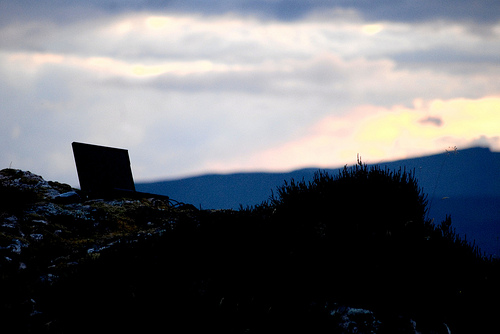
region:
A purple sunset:
[320, 86, 499, 163]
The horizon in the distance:
[135, 130, 497, 198]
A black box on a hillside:
[69, 137, 172, 221]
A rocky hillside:
[3, 162, 204, 329]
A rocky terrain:
[5, 168, 200, 332]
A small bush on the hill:
[255, 157, 450, 262]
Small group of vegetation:
[253, 164, 440, 259]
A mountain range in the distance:
[167, 144, 498, 182]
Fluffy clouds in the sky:
[17, 9, 392, 109]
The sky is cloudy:
[22, 12, 470, 124]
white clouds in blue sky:
[6, 15, 98, 65]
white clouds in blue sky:
[28, 58, 92, 109]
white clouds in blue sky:
[18, 101, 50, 166]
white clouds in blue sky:
[49, 5, 129, 62]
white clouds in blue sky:
[76, 78, 134, 113]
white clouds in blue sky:
[126, 62, 198, 150]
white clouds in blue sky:
[188, 25, 275, 105]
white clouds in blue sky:
[315, 35, 372, 93]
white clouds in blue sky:
[268, 48, 373, 145]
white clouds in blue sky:
[393, 11, 473, 111]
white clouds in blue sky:
[11, 42, 98, 90]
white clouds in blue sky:
[74, 76, 116, 98]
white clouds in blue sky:
[105, 26, 173, 75]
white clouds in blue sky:
[122, 74, 210, 116]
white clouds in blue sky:
[213, 78, 272, 141]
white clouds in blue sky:
[301, 31, 350, 86]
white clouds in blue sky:
[291, 87, 340, 137]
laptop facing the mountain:
[57, 132, 174, 219]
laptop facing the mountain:
[37, 61, 499, 248]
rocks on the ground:
[47, 189, 89, 219]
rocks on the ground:
[32, 181, 101, 230]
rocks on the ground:
[63, 186, 145, 262]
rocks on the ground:
[4, 207, 36, 254]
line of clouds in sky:
[16, 10, 492, 112]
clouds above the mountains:
[10, 19, 473, 124]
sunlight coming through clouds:
[303, 93, 482, 153]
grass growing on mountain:
[260, 156, 447, 233]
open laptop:
[74, 135, 169, 197]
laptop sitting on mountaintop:
[58, 130, 168, 207]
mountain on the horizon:
[144, 122, 496, 267]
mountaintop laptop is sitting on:
[7, 131, 489, 332]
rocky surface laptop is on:
[5, 157, 165, 276]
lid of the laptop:
[72, 135, 135, 190]